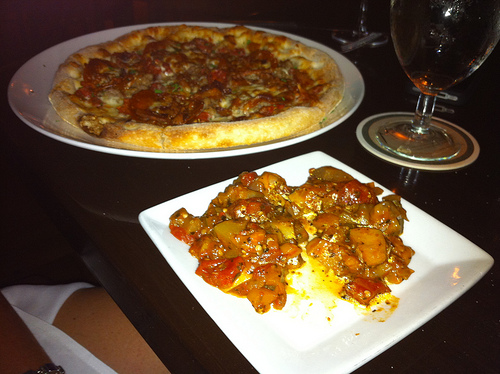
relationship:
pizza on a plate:
[50, 23, 345, 155] [9, 21, 367, 161]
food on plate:
[171, 167, 413, 311] [137, 151, 495, 372]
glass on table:
[376, 0, 499, 163] [9, 3, 498, 372]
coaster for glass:
[357, 112, 480, 173] [376, 0, 499, 163]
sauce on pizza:
[98, 41, 311, 122] [50, 23, 345, 155]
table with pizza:
[9, 3, 498, 372] [50, 23, 345, 155]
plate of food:
[137, 151, 495, 372] [171, 167, 413, 311]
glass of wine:
[376, 0, 499, 163] [393, 23, 498, 92]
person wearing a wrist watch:
[0, 282, 168, 372] [27, 365, 64, 372]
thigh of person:
[54, 286, 168, 372] [0, 282, 168, 372]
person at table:
[0, 282, 168, 372] [9, 3, 498, 372]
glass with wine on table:
[376, 0, 499, 163] [9, 3, 498, 372]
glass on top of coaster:
[376, 0, 499, 163] [357, 112, 480, 173]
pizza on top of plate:
[50, 23, 345, 155] [9, 21, 367, 161]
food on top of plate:
[171, 167, 413, 311] [137, 151, 495, 372]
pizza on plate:
[50, 23, 345, 155] [9, 21, 367, 161]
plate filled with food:
[137, 151, 495, 372] [171, 167, 413, 311]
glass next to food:
[376, 0, 499, 163] [171, 167, 413, 311]